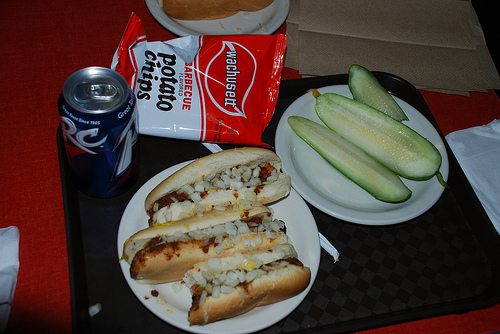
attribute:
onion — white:
[88, 303, 102, 318]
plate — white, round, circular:
[115, 159, 322, 334]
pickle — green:
[285, 115, 446, 205]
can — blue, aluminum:
[59, 64, 138, 201]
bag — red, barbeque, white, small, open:
[108, 12, 288, 150]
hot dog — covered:
[141, 146, 292, 227]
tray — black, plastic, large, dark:
[56, 71, 499, 331]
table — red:
[1, 0, 497, 333]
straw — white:
[200, 137, 339, 264]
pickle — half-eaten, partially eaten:
[348, 62, 410, 125]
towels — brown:
[284, 0, 499, 96]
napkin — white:
[443, 116, 499, 237]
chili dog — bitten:
[183, 244, 315, 327]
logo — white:
[204, 40, 257, 121]